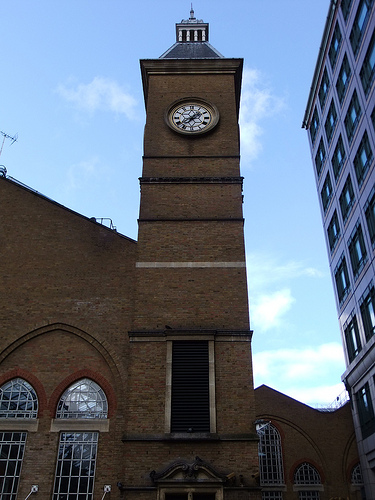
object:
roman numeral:
[181, 107, 186, 111]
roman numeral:
[201, 109, 207, 114]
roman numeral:
[201, 120, 209, 125]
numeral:
[188, 102, 194, 111]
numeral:
[174, 119, 182, 124]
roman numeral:
[188, 125, 193, 130]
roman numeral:
[195, 124, 203, 129]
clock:
[163, 95, 220, 136]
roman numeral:
[173, 116, 179, 119]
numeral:
[203, 115, 209, 120]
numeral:
[181, 122, 187, 130]